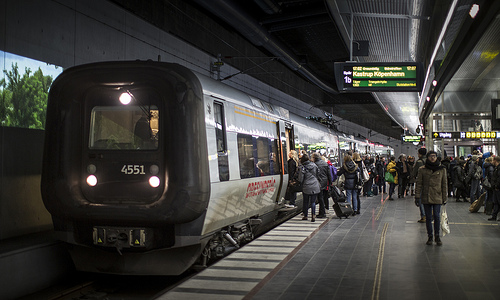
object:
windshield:
[86, 104, 161, 152]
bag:
[331, 185, 354, 219]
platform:
[155, 186, 499, 300]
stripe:
[364, 215, 389, 300]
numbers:
[121, 164, 145, 174]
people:
[286, 148, 396, 222]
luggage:
[311, 163, 328, 191]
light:
[86, 174, 98, 186]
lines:
[368, 221, 390, 299]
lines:
[405, 220, 500, 226]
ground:
[155, 187, 500, 300]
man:
[413, 150, 448, 247]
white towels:
[118, 92, 132, 106]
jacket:
[415, 165, 449, 204]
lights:
[118, 91, 135, 105]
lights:
[148, 175, 161, 188]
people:
[394, 147, 500, 222]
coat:
[414, 165, 449, 205]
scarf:
[424, 158, 446, 174]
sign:
[337, 61, 423, 93]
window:
[89, 102, 163, 154]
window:
[210, 99, 231, 182]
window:
[239, 134, 282, 179]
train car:
[41, 59, 295, 275]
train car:
[290, 112, 341, 189]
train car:
[336, 135, 356, 153]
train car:
[353, 140, 371, 156]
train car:
[374, 146, 398, 155]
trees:
[0, 59, 53, 130]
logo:
[245, 176, 277, 199]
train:
[34, 59, 396, 279]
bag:
[438, 203, 450, 238]